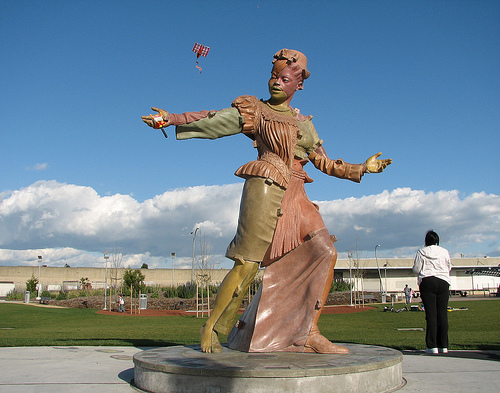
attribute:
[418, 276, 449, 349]
pants — black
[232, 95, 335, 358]
dress — brown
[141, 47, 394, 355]
statue — brown, green, pink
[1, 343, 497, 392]
ground — grey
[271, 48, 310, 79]
hat — brown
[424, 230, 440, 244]
hair — black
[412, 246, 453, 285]
shirt — white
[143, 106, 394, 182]
arms — spread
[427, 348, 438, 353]
shoe — white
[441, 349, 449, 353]
shoe — white